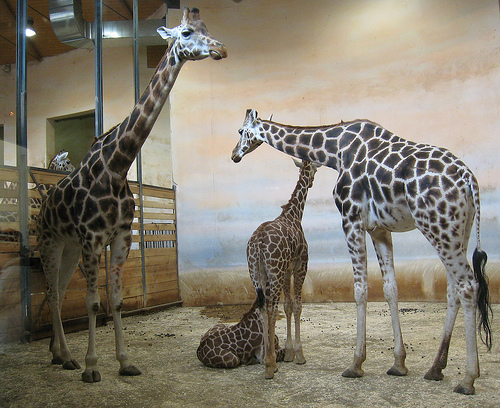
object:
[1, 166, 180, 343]
wooden enclosure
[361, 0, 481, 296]
pen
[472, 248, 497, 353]
hair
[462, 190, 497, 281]
tail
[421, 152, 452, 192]
ground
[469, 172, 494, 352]
tail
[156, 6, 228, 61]
head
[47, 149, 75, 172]
head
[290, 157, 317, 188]
head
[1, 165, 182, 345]
nearby enclosure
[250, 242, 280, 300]
tail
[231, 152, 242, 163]
mouth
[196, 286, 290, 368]
giraffe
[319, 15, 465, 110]
wall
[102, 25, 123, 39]
light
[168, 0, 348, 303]
pen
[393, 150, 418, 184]
spot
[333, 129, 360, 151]
spot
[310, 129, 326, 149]
spot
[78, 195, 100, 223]
spot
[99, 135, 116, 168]
spot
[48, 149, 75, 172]
giraffe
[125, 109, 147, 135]
spot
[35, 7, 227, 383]
giraffe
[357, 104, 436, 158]
ground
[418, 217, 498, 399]
leg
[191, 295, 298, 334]
stain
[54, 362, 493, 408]
floor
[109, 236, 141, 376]
legs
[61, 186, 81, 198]
spot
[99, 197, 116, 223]
spot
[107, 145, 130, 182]
spot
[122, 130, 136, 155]
spot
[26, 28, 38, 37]
light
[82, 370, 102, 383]
clove-hoof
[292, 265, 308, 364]
legs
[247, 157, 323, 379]
giraffe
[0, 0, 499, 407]
giraffe pen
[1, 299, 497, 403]
ground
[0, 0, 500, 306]
wall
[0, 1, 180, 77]
ceiling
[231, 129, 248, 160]
face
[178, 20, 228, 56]
face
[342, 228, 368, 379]
leg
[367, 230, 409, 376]
leg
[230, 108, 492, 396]
giraffe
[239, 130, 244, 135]
eye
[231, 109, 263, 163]
head